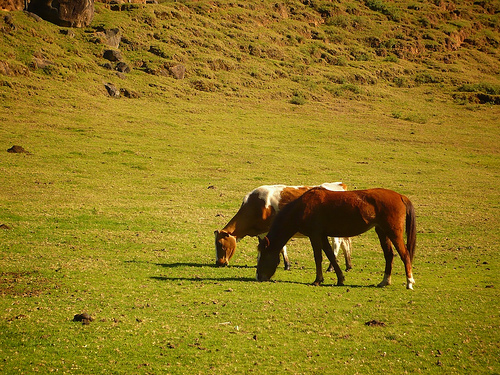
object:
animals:
[213, 182, 353, 273]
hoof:
[376, 277, 391, 287]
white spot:
[243, 184, 286, 214]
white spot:
[321, 182, 346, 191]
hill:
[0, 0, 193, 91]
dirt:
[71, 312, 94, 325]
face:
[258, 250, 276, 280]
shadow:
[147, 276, 261, 281]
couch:
[86, 27, 124, 48]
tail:
[398, 195, 418, 264]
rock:
[163, 60, 187, 80]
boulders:
[119, 88, 141, 99]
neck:
[235, 210, 246, 240]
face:
[217, 235, 233, 262]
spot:
[278, 187, 311, 210]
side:
[305, 188, 392, 234]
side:
[252, 186, 291, 209]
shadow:
[156, 263, 257, 269]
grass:
[231, 273, 235, 277]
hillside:
[442, 0, 499, 102]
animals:
[255, 185, 418, 289]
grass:
[4, 165, 14, 177]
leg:
[393, 230, 415, 290]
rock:
[364, 320, 382, 326]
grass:
[465, 359, 498, 370]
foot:
[406, 281, 415, 290]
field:
[3, 90, 495, 373]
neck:
[271, 206, 295, 248]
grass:
[484, 279, 498, 289]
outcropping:
[0, 1, 178, 97]